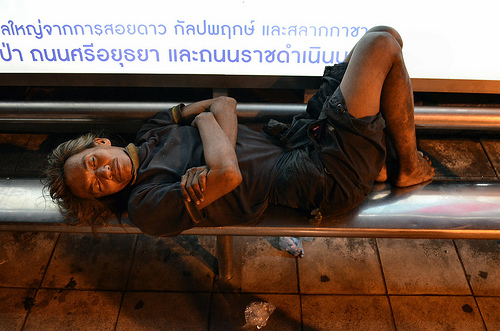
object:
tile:
[376, 238, 474, 296]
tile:
[297, 237, 386, 295]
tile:
[300, 295, 397, 331]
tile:
[387, 296, 488, 331]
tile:
[41, 232, 139, 291]